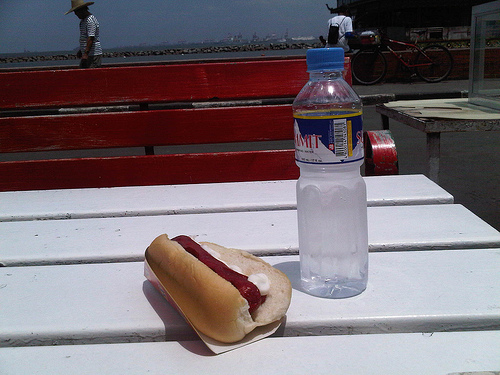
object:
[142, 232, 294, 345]
hot dog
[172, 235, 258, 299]
ketchup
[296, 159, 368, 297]
water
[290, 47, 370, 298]
bottle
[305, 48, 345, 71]
cap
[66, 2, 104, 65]
man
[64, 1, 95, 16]
cowboy hat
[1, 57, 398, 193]
bench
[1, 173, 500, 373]
table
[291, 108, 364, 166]
lable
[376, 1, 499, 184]
chair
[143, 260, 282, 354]
paper container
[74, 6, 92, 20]
head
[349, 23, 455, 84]
bike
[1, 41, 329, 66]
seawall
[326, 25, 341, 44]
backpack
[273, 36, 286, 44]
ship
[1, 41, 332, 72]
water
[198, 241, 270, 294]
mayo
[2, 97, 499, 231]
sidewalk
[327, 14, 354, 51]
shirt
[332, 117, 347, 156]
barcode